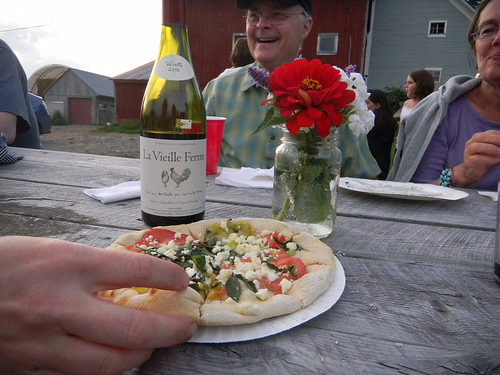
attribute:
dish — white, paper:
[175, 247, 349, 348]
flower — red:
[256, 55, 357, 141]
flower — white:
[341, 70, 378, 140]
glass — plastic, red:
[202, 113, 228, 179]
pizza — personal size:
[82, 183, 324, 343]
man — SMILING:
[236, 2, 311, 64]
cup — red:
[177, 113, 230, 180]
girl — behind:
[392, 65, 451, 187]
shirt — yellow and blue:
[184, 59, 379, 188]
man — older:
[192, 1, 380, 193]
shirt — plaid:
[201, 62, 381, 178]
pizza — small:
[93, 214, 336, 328]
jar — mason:
[253, 113, 379, 245]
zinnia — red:
[225, 51, 403, 156]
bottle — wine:
[143, 28, 207, 110]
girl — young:
[384, 40, 490, 210]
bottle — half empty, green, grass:
[138, 6, 210, 230]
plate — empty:
[331, 167, 456, 206]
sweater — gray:
[378, 70, 465, 165]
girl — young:
[398, 68, 435, 144]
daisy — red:
[263, 73, 366, 150]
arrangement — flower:
[250, 60, 373, 133]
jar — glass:
[276, 127, 341, 238]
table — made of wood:
[0, 148, 495, 375]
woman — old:
[441, 4, 499, 111]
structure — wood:
[22, 59, 140, 126]